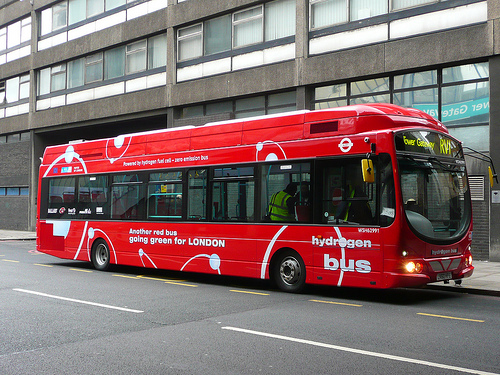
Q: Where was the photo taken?
A: It was taken at the road.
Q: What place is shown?
A: It is a road.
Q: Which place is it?
A: It is a road.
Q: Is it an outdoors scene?
A: Yes, it is outdoors.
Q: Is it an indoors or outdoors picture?
A: It is outdoors.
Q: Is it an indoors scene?
A: No, it is outdoors.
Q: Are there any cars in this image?
A: No, there are no cars.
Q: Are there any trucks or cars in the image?
A: No, there are no cars or trucks.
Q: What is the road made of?
A: The road is made of concrete.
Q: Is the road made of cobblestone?
A: No, the road is made of concrete.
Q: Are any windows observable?
A: Yes, there is a window.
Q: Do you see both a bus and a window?
A: Yes, there are both a window and a bus.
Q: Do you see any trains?
A: No, there are no trains.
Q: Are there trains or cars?
A: No, there are no trains or cars.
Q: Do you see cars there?
A: No, there are no cars.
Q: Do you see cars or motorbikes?
A: No, there are no cars or motorbikes.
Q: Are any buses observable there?
A: Yes, there is a bus.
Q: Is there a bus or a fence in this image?
A: Yes, there is a bus.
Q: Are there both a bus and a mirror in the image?
A: Yes, there are both a bus and a mirror.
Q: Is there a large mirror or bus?
A: Yes, there is a large bus.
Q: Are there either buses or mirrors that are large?
A: Yes, the bus is large.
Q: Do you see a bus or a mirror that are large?
A: Yes, the bus is large.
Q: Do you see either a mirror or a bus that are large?
A: Yes, the bus is large.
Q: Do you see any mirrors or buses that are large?
A: Yes, the bus is large.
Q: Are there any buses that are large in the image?
A: Yes, there is a large bus.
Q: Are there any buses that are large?
A: Yes, there is a bus that is large.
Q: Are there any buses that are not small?
A: Yes, there is a large bus.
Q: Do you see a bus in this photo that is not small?
A: Yes, there is a large bus.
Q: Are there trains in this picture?
A: No, there are no trains.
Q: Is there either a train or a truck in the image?
A: No, there are no trains or trucks.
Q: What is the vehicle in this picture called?
A: The vehicle is a bus.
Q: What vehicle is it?
A: The vehicle is a bus.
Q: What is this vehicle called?
A: This is a bus.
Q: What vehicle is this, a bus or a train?
A: This is a bus.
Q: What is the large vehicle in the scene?
A: The vehicle is a bus.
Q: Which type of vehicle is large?
A: The vehicle is a bus.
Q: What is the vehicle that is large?
A: The vehicle is a bus.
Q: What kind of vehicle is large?
A: The vehicle is a bus.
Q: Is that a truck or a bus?
A: That is a bus.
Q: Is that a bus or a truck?
A: That is a bus.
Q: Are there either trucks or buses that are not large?
A: No, there is a bus but it is large.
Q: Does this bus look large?
A: Yes, the bus is large.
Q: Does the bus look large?
A: Yes, the bus is large.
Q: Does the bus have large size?
A: Yes, the bus is large.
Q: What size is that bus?
A: The bus is large.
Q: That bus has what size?
A: The bus is large.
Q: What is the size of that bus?
A: The bus is large.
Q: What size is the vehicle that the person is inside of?
A: The bus is large.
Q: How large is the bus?
A: The bus is large.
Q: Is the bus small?
A: No, the bus is large.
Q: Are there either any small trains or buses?
A: No, there is a bus but it is large.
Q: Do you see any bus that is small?
A: No, there is a bus but it is large.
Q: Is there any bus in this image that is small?
A: No, there is a bus but it is large.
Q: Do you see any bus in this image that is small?
A: No, there is a bus but it is large.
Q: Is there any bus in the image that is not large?
A: No, there is a bus but it is large.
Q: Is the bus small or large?
A: The bus is large.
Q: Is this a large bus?
A: Yes, this is a large bus.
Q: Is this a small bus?
A: No, this is a large bus.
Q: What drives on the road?
A: The bus drives on the road.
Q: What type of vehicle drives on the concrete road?
A: The vehicle is a bus.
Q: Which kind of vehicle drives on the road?
A: The vehicle is a bus.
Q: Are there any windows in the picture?
A: Yes, there is a window.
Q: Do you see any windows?
A: Yes, there is a window.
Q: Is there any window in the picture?
A: Yes, there is a window.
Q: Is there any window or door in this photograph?
A: Yes, there is a window.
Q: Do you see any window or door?
A: Yes, there is a window.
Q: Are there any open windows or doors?
A: Yes, there is an open window.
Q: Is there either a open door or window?
A: Yes, there is an open window.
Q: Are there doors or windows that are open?
A: Yes, the window is open.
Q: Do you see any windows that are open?
A: Yes, there is an open window.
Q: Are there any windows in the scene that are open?
A: Yes, there is a window that is open.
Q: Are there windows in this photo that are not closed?
A: Yes, there is a open window.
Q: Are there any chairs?
A: No, there are no chairs.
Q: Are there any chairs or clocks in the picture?
A: No, there are no chairs or clocks.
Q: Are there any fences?
A: No, there are no fences.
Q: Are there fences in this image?
A: No, there are no fences.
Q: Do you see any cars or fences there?
A: No, there are no fences or cars.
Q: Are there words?
A: Yes, there are words.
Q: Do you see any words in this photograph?
A: Yes, there are words.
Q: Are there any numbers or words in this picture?
A: Yes, there are words.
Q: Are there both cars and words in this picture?
A: No, there are words but no cars.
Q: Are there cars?
A: No, there are no cars.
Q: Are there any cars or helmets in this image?
A: No, there are no cars or helmets.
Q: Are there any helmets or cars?
A: No, there are no cars or helmets.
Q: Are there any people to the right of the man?
A: Yes, there is a person to the right of the man.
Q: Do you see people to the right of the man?
A: Yes, there is a person to the right of the man.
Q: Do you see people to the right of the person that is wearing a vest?
A: Yes, there is a person to the right of the man.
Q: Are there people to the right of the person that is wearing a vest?
A: Yes, there is a person to the right of the man.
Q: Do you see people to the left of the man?
A: No, the person is to the right of the man.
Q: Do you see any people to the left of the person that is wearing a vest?
A: No, the person is to the right of the man.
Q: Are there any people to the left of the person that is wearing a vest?
A: No, the person is to the right of the man.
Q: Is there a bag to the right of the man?
A: No, there is a person to the right of the man.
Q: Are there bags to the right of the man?
A: No, there is a person to the right of the man.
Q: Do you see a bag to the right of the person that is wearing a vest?
A: No, there is a person to the right of the man.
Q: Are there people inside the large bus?
A: Yes, there is a person inside the bus.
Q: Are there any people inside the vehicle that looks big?
A: Yes, there is a person inside the bus.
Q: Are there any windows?
A: Yes, there is a window.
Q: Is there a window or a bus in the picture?
A: Yes, there is a window.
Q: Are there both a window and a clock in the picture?
A: No, there is a window but no clocks.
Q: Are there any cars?
A: No, there are no cars.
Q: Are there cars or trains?
A: No, there are no cars or trains.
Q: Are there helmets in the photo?
A: No, there are no helmets.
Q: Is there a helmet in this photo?
A: No, there are no helmets.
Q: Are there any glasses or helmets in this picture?
A: No, there are no helmets or glasses.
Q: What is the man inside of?
A: The man is inside the bus.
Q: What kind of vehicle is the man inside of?
A: The man is inside the bus.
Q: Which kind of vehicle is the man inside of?
A: The man is inside the bus.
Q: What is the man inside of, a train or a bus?
A: The man is inside a bus.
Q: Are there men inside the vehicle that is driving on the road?
A: Yes, there is a man inside the bus.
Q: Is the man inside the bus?
A: Yes, the man is inside the bus.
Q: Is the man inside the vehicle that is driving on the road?
A: Yes, the man is inside the bus.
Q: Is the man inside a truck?
A: No, the man is inside the bus.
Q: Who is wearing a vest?
A: The man is wearing a vest.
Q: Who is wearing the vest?
A: The man is wearing a vest.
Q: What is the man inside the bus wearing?
A: The man is wearing a vest.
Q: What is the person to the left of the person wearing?
A: The man is wearing a vest.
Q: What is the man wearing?
A: The man is wearing a vest.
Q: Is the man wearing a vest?
A: Yes, the man is wearing a vest.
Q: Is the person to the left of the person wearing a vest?
A: Yes, the man is wearing a vest.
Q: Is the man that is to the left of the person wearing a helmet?
A: No, the man is wearing a vest.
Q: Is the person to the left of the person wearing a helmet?
A: No, the man is wearing a vest.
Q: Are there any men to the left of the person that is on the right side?
A: Yes, there is a man to the left of the person.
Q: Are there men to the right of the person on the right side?
A: No, the man is to the left of the person.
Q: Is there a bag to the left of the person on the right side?
A: No, there is a man to the left of the person.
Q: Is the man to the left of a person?
A: Yes, the man is to the left of a person.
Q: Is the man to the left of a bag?
A: No, the man is to the left of a person.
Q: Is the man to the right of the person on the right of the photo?
A: No, the man is to the left of the person.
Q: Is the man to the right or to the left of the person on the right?
A: The man is to the left of the person.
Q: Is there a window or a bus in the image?
A: Yes, there is a window.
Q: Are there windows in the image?
A: Yes, there is a window.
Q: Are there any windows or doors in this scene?
A: Yes, there is a window.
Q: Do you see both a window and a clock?
A: No, there is a window but no clocks.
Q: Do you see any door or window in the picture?
A: Yes, there is a window.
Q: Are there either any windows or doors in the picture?
A: Yes, there is a window.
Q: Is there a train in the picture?
A: No, there are no trains.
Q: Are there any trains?
A: No, there are no trains.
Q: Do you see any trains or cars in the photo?
A: No, there are no trains or cars.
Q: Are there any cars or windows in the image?
A: Yes, there is a window.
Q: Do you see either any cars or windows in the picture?
A: Yes, there is a window.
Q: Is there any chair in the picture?
A: No, there are no chairs.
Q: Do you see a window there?
A: Yes, there is a window.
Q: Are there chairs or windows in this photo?
A: Yes, there is a window.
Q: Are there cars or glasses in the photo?
A: No, there are no cars or glasses.